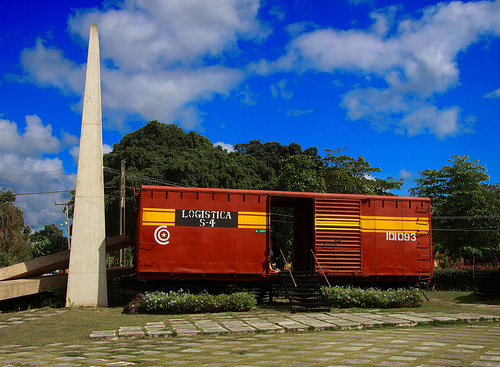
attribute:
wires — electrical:
[103, 164, 188, 196]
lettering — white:
[384, 229, 416, 241]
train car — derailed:
[126, 171, 446, 284]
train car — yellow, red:
[129, 180, 441, 293]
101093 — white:
[383, 229, 417, 242]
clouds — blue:
[285, 17, 483, 99]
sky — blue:
[194, 50, 413, 140]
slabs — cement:
[1, 250, 77, 300]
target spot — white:
[152, 222, 174, 246]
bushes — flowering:
[138, 285, 258, 314]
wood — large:
[3, 247, 58, 327]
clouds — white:
[109, 8, 493, 109]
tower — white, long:
[67, 21, 108, 311]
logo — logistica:
[174, 206, 239, 226]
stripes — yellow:
[142, 204, 431, 233]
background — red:
[364, 230, 428, 270]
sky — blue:
[1, 2, 499, 241]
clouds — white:
[105, 6, 401, 88]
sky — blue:
[9, 6, 495, 134]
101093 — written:
[380, 225, 420, 244]